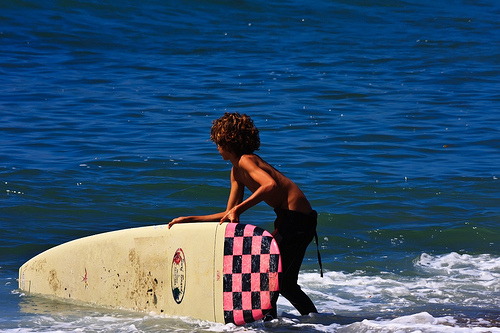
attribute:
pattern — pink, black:
[220, 222, 285, 324]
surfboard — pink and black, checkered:
[15, 216, 285, 327]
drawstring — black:
[312, 230, 324, 275]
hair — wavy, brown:
[209, 107, 261, 156]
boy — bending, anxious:
[188, 87, 425, 309]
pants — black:
[269, 208, 324, 314]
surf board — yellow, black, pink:
[7, 211, 292, 331]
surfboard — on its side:
[8, 179, 309, 329]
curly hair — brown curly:
[214, 112, 261, 144]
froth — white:
[339, 275, 434, 326]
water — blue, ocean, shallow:
[5, 3, 498, 324]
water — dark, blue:
[244, 29, 494, 219]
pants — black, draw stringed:
[196, 195, 360, 308]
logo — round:
[162, 246, 193, 311]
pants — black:
[259, 202, 322, 312]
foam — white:
[286, 251, 483, 330]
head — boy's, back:
[206, 105, 257, 161]